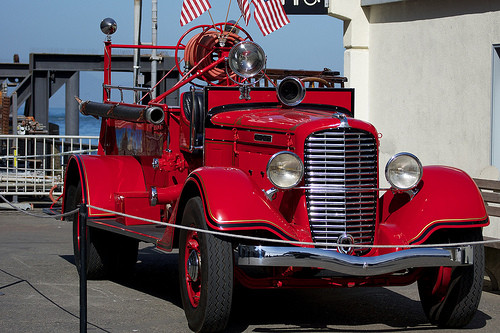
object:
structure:
[0, 52, 183, 212]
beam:
[65, 71, 80, 144]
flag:
[177, 0, 213, 29]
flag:
[236, 0, 253, 29]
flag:
[250, 0, 291, 38]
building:
[326, 0, 499, 294]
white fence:
[0, 132, 98, 203]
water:
[19, 106, 102, 146]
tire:
[178, 195, 237, 332]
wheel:
[173, 20, 252, 86]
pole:
[77, 94, 165, 126]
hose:
[182, 29, 248, 81]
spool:
[172, 22, 261, 90]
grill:
[303, 127, 378, 257]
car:
[42, 21, 489, 333]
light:
[266, 148, 306, 188]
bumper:
[235, 245, 473, 278]